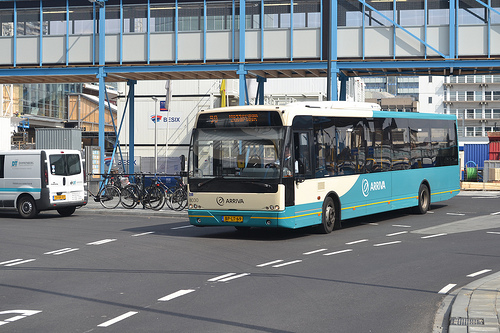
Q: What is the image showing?
A: It is showing a road.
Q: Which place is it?
A: It is a road.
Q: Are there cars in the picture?
A: No, there are no cars.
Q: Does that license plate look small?
A: Yes, the license plate is small.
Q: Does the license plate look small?
A: Yes, the license plate is small.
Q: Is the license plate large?
A: No, the license plate is small.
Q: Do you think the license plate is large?
A: No, the license plate is small.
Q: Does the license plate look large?
A: No, the license plate is small.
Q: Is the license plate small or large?
A: The license plate is small.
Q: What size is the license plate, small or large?
A: The license plate is small.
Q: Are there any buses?
A: Yes, there is a bus.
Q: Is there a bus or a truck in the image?
A: Yes, there is a bus.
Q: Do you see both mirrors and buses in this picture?
A: Yes, there are both a bus and a mirror.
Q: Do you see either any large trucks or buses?
A: Yes, there is a large bus.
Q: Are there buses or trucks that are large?
A: Yes, the bus is large.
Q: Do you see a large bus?
A: Yes, there is a large bus.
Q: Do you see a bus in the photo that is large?
A: Yes, there is a bus that is large.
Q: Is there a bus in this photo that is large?
A: Yes, there is a bus that is large.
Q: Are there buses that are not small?
A: Yes, there is a large bus.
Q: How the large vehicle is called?
A: The vehicle is a bus.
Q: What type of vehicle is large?
A: The vehicle is a bus.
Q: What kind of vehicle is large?
A: The vehicle is a bus.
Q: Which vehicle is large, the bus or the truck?
A: The bus is large.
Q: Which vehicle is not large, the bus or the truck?
A: The truck is not large.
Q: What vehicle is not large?
A: The vehicle is a truck.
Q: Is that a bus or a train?
A: That is a bus.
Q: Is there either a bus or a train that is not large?
A: No, there is a bus but it is large.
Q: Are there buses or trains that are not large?
A: No, there is a bus but it is large.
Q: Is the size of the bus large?
A: Yes, the bus is large.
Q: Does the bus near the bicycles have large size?
A: Yes, the bus is large.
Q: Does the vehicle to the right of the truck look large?
A: Yes, the bus is large.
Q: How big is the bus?
A: The bus is large.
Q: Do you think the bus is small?
A: No, the bus is large.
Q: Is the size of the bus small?
A: No, the bus is large.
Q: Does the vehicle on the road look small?
A: No, the bus is large.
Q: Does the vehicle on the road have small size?
A: No, the bus is large.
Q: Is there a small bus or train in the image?
A: No, there is a bus but it is large.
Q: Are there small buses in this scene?
A: No, there is a bus but it is large.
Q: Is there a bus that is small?
A: No, there is a bus but it is large.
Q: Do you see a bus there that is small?
A: No, there is a bus but it is large.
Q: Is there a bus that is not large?
A: No, there is a bus but it is large.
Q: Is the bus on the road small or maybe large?
A: The bus is large.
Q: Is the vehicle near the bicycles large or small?
A: The bus is large.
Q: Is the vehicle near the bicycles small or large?
A: The bus is large.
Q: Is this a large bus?
A: Yes, this is a large bus.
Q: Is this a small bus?
A: No, this is a large bus.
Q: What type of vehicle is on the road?
A: The vehicle is a bus.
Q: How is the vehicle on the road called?
A: The vehicle is a bus.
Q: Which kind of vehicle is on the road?
A: The vehicle is a bus.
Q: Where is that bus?
A: The bus is on the road.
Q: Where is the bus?
A: The bus is on the road.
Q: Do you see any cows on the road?
A: No, there is a bus on the road.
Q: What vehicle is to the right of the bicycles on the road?
A: The vehicle is a bus.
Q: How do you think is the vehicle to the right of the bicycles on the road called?
A: The vehicle is a bus.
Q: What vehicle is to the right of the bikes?
A: The vehicle is a bus.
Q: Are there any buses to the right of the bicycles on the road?
A: Yes, there is a bus to the right of the bikes.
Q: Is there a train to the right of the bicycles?
A: No, there is a bus to the right of the bicycles.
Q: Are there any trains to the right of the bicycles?
A: No, there is a bus to the right of the bicycles.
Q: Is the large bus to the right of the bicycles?
A: Yes, the bus is to the right of the bicycles.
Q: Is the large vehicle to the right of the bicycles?
A: Yes, the bus is to the right of the bicycles.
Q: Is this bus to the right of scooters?
A: No, the bus is to the right of the bicycles.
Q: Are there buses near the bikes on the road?
A: Yes, there is a bus near the bicycles.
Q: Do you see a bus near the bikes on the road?
A: Yes, there is a bus near the bicycles.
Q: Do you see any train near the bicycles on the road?
A: No, there is a bus near the bikes.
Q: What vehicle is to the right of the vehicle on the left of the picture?
A: The vehicle is a bus.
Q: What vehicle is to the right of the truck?
A: The vehicle is a bus.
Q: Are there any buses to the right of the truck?
A: Yes, there is a bus to the right of the truck.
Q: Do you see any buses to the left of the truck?
A: No, the bus is to the right of the truck.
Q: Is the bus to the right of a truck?
A: Yes, the bus is to the right of a truck.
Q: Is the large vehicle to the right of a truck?
A: Yes, the bus is to the right of a truck.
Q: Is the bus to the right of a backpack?
A: No, the bus is to the right of a truck.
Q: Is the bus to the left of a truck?
A: No, the bus is to the right of a truck.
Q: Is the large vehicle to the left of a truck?
A: No, the bus is to the right of a truck.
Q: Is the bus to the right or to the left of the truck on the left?
A: The bus is to the right of the truck.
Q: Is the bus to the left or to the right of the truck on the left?
A: The bus is to the right of the truck.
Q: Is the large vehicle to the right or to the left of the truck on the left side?
A: The bus is to the right of the truck.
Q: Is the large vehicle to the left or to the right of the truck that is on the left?
A: The bus is to the right of the truck.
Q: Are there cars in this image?
A: No, there are no cars.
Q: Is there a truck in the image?
A: Yes, there is a truck.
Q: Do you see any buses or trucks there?
A: Yes, there is a truck.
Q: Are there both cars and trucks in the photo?
A: No, there is a truck but no cars.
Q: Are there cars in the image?
A: No, there are no cars.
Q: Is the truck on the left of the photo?
A: Yes, the truck is on the left of the image.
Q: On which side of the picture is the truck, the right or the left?
A: The truck is on the left of the image.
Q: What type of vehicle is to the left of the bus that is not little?
A: The vehicle is a truck.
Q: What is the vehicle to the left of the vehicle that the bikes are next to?
A: The vehicle is a truck.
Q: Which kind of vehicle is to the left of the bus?
A: The vehicle is a truck.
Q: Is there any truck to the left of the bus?
A: Yes, there is a truck to the left of the bus.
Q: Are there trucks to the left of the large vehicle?
A: Yes, there is a truck to the left of the bus.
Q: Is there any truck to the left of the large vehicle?
A: Yes, there is a truck to the left of the bus.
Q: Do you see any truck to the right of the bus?
A: No, the truck is to the left of the bus.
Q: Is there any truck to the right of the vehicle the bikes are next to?
A: No, the truck is to the left of the bus.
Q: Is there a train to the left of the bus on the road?
A: No, there is a truck to the left of the bus.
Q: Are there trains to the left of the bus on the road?
A: No, there is a truck to the left of the bus.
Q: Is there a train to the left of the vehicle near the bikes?
A: No, there is a truck to the left of the bus.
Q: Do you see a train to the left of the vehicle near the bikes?
A: No, there is a truck to the left of the bus.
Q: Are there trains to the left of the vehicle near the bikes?
A: No, there is a truck to the left of the bus.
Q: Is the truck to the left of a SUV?
A: No, the truck is to the left of the bus.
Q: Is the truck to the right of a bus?
A: No, the truck is to the left of a bus.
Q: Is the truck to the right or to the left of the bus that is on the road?
A: The truck is to the left of the bus.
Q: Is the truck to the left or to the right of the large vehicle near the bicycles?
A: The truck is to the left of the bus.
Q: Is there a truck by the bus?
A: Yes, there is a truck by the bus.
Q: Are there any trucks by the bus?
A: Yes, there is a truck by the bus.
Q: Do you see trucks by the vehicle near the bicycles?
A: Yes, there is a truck by the bus.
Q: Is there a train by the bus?
A: No, there is a truck by the bus.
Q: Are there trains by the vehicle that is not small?
A: No, there is a truck by the bus.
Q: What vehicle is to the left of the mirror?
A: The vehicle is a truck.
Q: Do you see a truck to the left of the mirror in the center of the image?
A: Yes, there is a truck to the left of the mirror.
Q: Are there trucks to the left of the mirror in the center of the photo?
A: Yes, there is a truck to the left of the mirror.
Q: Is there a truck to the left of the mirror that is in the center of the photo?
A: Yes, there is a truck to the left of the mirror.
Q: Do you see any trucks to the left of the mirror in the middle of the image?
A: Yes, there is a truck to the left of the mirror.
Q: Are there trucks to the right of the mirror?
A: No, the truck is to the left of the mirror.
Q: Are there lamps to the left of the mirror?
A: No, there is a truck to the left of the mirror.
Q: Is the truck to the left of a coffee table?
A: No, the truck is to the left of the mirror.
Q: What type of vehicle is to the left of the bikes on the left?
A: The vehicle is a truck.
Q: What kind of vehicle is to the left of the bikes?
A: The vehicle is a truck.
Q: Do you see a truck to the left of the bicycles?
A: Yes, there is a truck to the left of the bicycles.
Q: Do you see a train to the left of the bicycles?
A: No, there is a truck to the left of the bicycles.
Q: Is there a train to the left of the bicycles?
A: No, there is a truck to the left of the bicycles.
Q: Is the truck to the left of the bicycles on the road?
A: Yes, the truck is to the left of the bikes.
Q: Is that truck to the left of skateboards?
A: No, the truck is to the left of the bikes.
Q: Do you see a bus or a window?
A: Yes, there is a window.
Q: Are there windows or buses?
A: Yes, there is a window.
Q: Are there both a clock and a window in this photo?
A: No, there is a window but no clocks.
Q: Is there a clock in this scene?
A: No, there are no clocks.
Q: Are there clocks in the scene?
A: No, there are no clocks.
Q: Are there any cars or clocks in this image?
A: No, there are no clocks or cars.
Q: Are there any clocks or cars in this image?
A: No, there are no clocks or cars.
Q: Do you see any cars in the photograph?
A: No, there are no cars.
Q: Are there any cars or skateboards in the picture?
A: No, there are no cars or skateboards.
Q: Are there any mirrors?
A: Yes, there is a mirror.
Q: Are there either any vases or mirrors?
A: Yes, there is a mirror.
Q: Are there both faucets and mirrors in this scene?
A: No, there is a mirror but no faucets.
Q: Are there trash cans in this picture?
A: No, there are no trash cans.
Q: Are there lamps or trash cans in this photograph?
A: No, there are no trash cans or lamps.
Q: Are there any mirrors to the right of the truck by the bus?
A: Yes, there is a mirror to the right of the truck.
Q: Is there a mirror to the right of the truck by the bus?
A: Yes, there is a mirror to the right of the truck.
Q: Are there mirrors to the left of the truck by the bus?
A: No, the mirror is to the right of the truck.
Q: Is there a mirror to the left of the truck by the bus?
A: No, the mirror is to the right of the truck.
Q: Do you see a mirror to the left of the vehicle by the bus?
A: No, the mirror is to the right of the truck.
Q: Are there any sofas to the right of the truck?
A: No, there is a mirror to the right of the truck.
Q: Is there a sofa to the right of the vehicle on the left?
A: No, there is a mirror to the right of the truck.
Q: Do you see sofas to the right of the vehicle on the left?
A: No, there is a mirror to the right of the truck.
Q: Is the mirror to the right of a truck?
A: Yes, the mirror is to the right of a truck.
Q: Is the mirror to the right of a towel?
A: No, the mirror is to the right of a truck.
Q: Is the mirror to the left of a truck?
A: No, the mirror is to the right of a truck.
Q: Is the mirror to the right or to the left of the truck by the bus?
A: The mirror is to the right of the truck.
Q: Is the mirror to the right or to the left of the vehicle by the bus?
A: The mirror is to the right of the truck.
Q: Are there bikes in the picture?
A: Yes, there are bikes.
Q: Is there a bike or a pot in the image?
A: Yes, there are bikes.